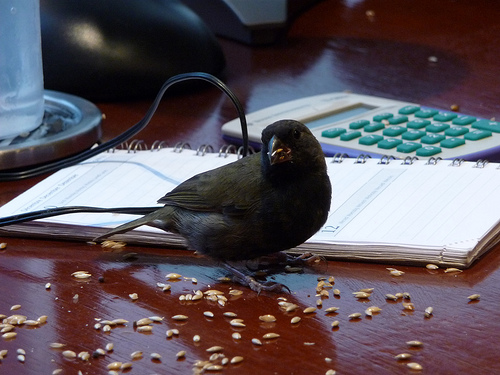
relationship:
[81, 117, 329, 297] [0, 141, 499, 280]
bird near book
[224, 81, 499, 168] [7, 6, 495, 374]
calculator on table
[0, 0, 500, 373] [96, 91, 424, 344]
desk made out of wood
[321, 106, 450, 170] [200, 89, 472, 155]
buttons on calculator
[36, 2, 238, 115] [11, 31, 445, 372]
mouse on table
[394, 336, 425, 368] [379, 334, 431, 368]
pieces of birdseed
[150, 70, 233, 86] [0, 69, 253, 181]
part of wire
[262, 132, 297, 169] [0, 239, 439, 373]
beak full of food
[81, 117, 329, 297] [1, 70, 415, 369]
bird on desk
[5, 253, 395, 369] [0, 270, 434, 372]
seeds on desk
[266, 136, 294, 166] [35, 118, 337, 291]
beak of bird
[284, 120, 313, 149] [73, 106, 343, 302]
eye of bird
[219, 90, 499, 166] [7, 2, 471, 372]
calculator on desk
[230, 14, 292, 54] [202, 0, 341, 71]
base of phone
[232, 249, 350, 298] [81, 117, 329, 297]
claw of bird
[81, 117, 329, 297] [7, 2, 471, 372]
bird on desk